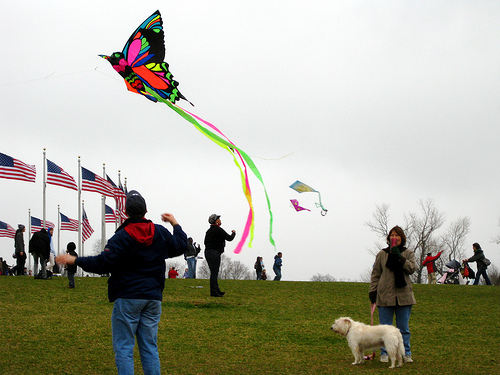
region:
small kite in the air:
[102, 5, 203, 120]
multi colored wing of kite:
[124, 15, 171, 69]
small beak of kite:
[97, 53, 119, 61]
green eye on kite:
[110, 49, 124, 60]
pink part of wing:
[114, 32, 146, 70]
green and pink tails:
[164, 102, 291, 272]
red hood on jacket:
[128, 216, 163, 240]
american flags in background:
[2, 143, 120, 208]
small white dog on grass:
[330, 322, 410, 360]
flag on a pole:
[31, 150, 76, 195]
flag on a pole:
[66, 156, 106, 199]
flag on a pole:
[73, 196, 98, 241]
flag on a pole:
[51, 206, 76, 236]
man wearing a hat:
[60, 191, 192, 372]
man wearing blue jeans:
[57, 187, 195, 372]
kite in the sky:
[81, 3, 202, 138]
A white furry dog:
[326, 310, 411, 371]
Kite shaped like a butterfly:
[98, 6, 197, 123]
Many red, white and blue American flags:
[0, 146, 131, 276]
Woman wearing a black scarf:
[369, 221, 418, 295]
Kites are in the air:
[97, 8, 333, 262]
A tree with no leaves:
[364, 201, 471, 285]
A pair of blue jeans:
[109, 293, 165, 373]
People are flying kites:
[53, 7, 332, 299]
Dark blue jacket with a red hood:
[74, 216, 192, 304]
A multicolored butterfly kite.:
[86, 9, 297, 249]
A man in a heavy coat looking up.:
[68, 177, 205, 369]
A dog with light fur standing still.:
[329, 312, 416, 366]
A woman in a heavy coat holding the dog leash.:
[339, 213, 421, 363]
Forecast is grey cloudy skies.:
[217, 16, 481, 149]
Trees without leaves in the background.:
[363, 198, 465, 289]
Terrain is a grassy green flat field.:
[32, 269, 485, 374]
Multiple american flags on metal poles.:
[6, 147, 138, 270]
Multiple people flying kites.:
[189, 169, 336, 289]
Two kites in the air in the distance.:
[283, 169, 335, 226]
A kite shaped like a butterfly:
[99, 9, 279, 255]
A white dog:
[331, 315, 411, 370]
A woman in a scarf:
[368, 225, 415, 362]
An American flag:
[0, 150, 36, 183]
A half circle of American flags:
[0, 145, 132, 280]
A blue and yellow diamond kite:
[288, 179, 328, 217]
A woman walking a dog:
[326, 223, 418, 369]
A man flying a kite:
[52, 8, 277, 374]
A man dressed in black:
[204, 214, 236, 298]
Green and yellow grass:
[0, 275, 498, 374]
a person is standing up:
[65, 184, 191, 374]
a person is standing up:
[363, 220, 414, 363]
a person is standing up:
[471, 227, 493, 290]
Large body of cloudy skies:
[284, 24, 406, 131]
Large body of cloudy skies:
[348, 83, 461, 187]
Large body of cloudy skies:
[322, 68, 417, 156]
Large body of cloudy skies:
[20, 63, 80, 120]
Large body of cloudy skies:
[384, 65, 466, 163]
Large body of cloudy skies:
[233, 55, 347, 120]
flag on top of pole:
[29, 147, 80, 196]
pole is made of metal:
[43, 144, 48, 268]